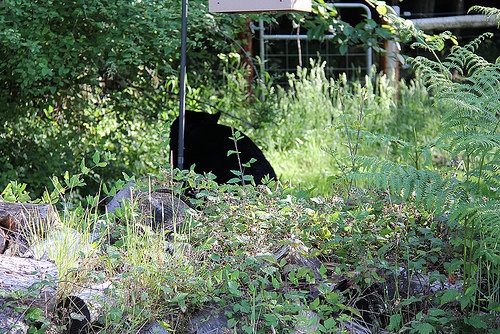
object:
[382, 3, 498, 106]
post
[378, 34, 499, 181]
plant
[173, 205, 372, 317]
leaves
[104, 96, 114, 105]
leaf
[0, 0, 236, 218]
leaf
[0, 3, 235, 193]
green leaves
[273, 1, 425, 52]
leaves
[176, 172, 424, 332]
leaves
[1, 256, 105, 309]
logs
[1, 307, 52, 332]
logs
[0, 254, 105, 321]
gray logs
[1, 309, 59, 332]
gray logs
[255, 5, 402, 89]
fence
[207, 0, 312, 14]
bird house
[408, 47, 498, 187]
fern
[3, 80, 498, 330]
garden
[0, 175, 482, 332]
pile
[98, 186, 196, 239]
white stone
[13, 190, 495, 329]
ground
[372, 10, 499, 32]
railing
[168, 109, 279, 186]
cat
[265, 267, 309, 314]
rock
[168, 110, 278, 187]
bear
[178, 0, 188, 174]
pole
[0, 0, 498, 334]
photo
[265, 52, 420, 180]
twig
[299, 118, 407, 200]
grasses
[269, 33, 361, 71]
gate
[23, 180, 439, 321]
ivy